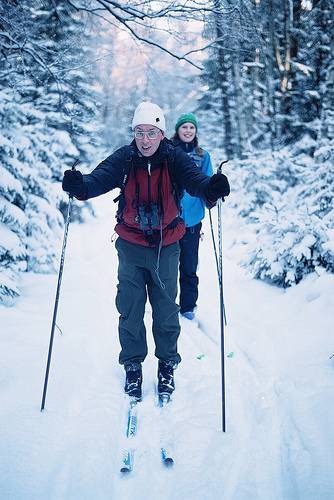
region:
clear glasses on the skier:
[132, 128, 161, 140]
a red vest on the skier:
[113, 139, 186, 246]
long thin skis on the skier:
[120, 373, 172, 472]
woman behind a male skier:
[169, 113, 213, 175]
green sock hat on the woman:
[175, 113, 195, 129]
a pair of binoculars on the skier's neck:
[135, 205, 164, 232]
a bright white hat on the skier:
[131, 102, 164, 130]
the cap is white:
[115, 99, 168, 136]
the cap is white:
[122, 93, 176, 141]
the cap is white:
[112, 88, 182, 145]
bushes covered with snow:
[215, 129, 322, 264]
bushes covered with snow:
[217, 147, 331, 301]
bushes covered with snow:
[215, 131, 308, 273]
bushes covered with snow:
[217, 128, 314, 280]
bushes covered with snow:
[209, 139, 309, 279]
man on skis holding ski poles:
[27, 101, 234, 472]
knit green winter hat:
[174, 112, 198, 132]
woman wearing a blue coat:
[168, 110, 215, 319]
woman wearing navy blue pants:
[166, 111, 216, 319]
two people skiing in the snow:
[30, 99, 234, 476]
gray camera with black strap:
[127, 144, 165, 238]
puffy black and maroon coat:
[80, 139, 215, 246]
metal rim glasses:
[131, 128, 162, 139]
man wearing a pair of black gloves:
[62, 100, 230, 396]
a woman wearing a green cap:
[171, 99, 209, 150]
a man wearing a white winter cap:
[126, 96, 161, 155]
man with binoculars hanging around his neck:
[78, 88, 219, 248]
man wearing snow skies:
[72, 111, 206, 470]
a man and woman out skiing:
[40, 95, 265, 484]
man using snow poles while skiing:
[40, 145, 248, 432]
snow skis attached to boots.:
[115, 356, 193, 472]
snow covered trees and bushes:
[213, 2, 328, 267]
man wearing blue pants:
[107, 233, 201, 371]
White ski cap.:
[131, 101, 165, 133]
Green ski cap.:
[174, 111, 199, 132]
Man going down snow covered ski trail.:
[38, 99, 230, 475]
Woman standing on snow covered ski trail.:
[152, 110, 231, 326]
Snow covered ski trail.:
[0, 158, 333, 497]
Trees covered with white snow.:
[0, 0, 106, 308]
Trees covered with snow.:
[204, 0, 332, 288]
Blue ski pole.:
[35, 156, 86, 418]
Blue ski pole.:
[213, 154, 232, 437]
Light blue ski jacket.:
[166, 141, 215, 229]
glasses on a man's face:
[134, 131, 159, 137]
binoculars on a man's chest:
[135, 198, 160, 230]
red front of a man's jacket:
[118, 158, 185, 245]